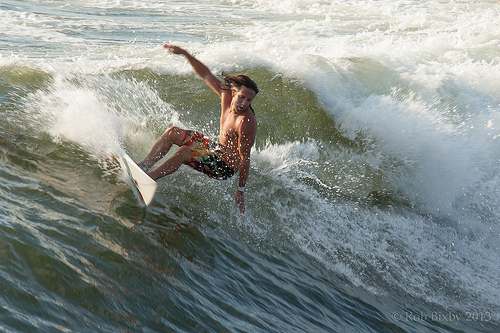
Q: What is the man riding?
A: Surfboard.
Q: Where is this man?
A: Ocean.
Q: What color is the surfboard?
A: White.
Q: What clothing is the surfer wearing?
A: Bathing suit.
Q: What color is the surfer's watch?
A: White.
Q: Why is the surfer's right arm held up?
A: Balance.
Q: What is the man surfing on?
A: Wave.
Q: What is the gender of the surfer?
A: Male.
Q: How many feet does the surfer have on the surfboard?
A: 2.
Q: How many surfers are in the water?
A: 1.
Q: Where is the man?
A: In the ocean.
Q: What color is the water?
A: Green.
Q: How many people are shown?
A: 1.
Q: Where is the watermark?
A: Bottom right.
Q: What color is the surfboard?
A: White.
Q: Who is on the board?
A: A man.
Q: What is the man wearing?
A: Swim trunks.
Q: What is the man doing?
A: Surfing.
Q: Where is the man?
A: In the ocean.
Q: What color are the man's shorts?
A: Red and blue.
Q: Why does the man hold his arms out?
A: To balance the himself.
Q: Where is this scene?
A: Near a beach.